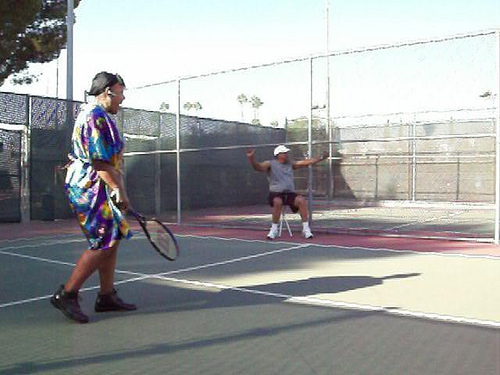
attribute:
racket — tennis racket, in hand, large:
[105, 189, 183, 265]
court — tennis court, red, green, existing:
[1, 202, 499, 374]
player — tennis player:
[48, 69, 184, 327]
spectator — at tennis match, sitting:
[242, 139, 333, 242]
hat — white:
[271, 144, 291, 157]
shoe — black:
[50, 284, 90, 324]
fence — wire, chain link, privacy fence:
[1, 88, 499, 224]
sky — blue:
[0, 1, 499, 122]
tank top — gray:
[265, 159, 295, 193]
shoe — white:
[264, 224, 279, 242]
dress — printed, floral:
[63, 99, 139, 252]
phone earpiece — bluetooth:
[106, 86, 120, 100]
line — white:
[1, 271, 150, 316]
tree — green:
[0, 1, 83, 92]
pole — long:
[325, 2, 331, 165]